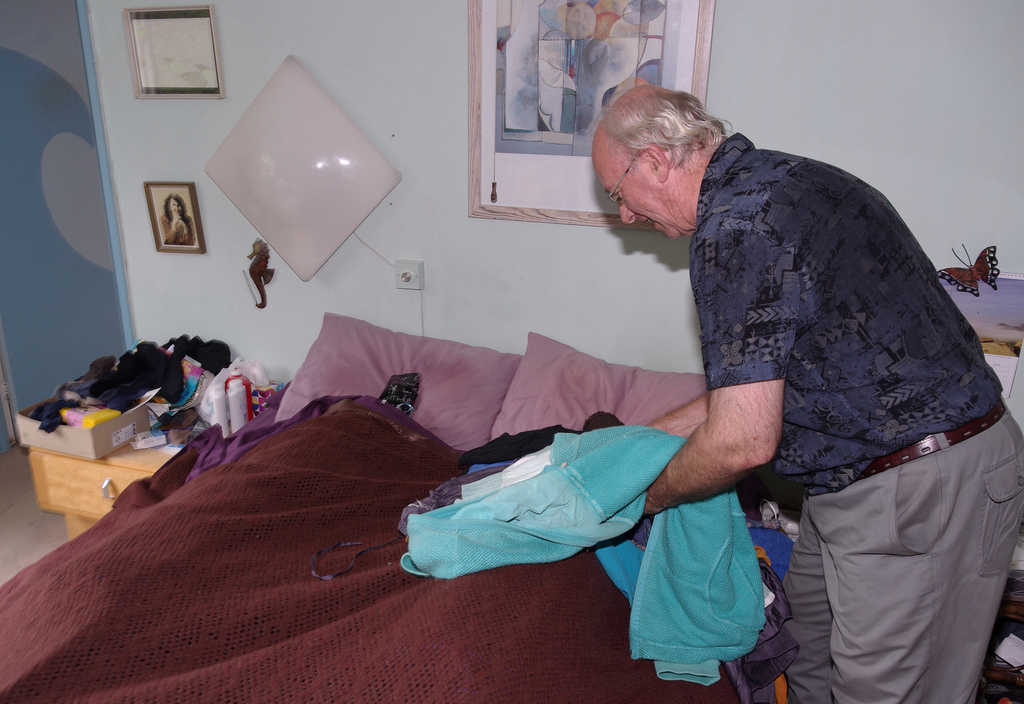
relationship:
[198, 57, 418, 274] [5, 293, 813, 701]
light above bed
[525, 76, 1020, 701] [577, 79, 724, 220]
man has head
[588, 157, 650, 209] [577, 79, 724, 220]
glasses are on head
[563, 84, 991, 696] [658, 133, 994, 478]
man wearing shirt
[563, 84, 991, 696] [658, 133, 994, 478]
man have shirt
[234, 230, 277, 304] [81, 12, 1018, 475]
seahorse on wall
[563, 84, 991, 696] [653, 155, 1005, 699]
man holding clothing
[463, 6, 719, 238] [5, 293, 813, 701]
picture above bed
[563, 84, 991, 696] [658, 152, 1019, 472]
man wearing shirt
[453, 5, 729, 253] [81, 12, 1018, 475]
picture on wall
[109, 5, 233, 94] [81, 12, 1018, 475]
picture on wall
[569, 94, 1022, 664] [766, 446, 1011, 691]
man wearing pants